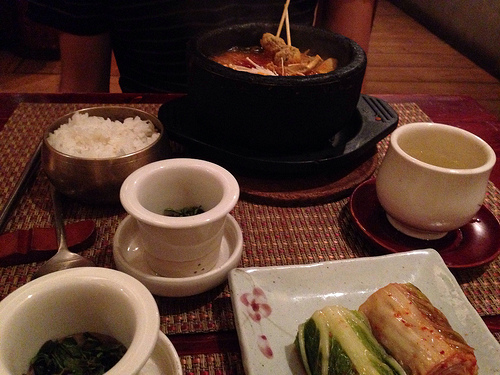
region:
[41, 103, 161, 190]
a bowl of white rice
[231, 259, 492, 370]
a plate of asian cuisine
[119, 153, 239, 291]
a thin white cup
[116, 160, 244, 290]
thin white cup on a ploatter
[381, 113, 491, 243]
a white tea cup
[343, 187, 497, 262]
a red plate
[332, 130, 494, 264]
a white tea cup on a red platter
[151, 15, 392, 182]
a black pot on a pot holder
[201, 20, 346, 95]
a pot of spicy looking food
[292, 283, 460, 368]
a plate of kimchi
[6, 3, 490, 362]
a traditional korean meal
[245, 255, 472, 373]
a plate of kimchi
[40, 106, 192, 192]
a bowl of rice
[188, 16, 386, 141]
a clay pot of stew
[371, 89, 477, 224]
a cup of green tea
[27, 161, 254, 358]
two dishes of ban chan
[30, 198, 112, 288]
a spoon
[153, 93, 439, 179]
a plate for carrying a hot dish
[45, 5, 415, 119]
a man in a black shirt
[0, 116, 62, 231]
a set of chopsticks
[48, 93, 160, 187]
rice in a bowl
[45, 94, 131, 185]
rice in a bowl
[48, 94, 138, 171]
rice in a bowl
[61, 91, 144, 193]
rice in a bowl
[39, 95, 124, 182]
rice in a bowl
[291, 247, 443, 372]
food on the plate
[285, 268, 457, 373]
food on the plate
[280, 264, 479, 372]
food on the plate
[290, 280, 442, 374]
food on the plate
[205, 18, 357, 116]
a portion of food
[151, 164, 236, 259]
a portion of food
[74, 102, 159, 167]
a portion of food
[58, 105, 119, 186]
a portion of food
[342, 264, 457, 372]
a portion of food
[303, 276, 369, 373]
a portion of food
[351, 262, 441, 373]
a portion of food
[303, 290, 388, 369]
a portion of food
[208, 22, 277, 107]
a portion of food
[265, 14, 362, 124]
a portion of food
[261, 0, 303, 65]
Mini meatballs with toothpicks sticking out of them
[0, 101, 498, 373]
Woven dark red and brown colored placemat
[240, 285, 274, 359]
Pink flower desing on the side of a square plate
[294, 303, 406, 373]
Green vegetable that is rolled and has wet exterior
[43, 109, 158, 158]
Medium serving of sticky white rice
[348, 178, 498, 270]
Dark maroon round saucer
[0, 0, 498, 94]
Brown hardwood floor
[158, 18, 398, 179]
Black bowl with a base used for serving hot food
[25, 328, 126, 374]
Wet green leafy substance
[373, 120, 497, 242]
Cream colored ceramic bowl with clear liquid in it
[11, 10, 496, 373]
a selection of food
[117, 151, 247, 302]
bowl in a saucer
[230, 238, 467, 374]
a plate of food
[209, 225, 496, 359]
the plate is square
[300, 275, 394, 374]
a green and tan veggie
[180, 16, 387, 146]
a black bowl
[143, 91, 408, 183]
plate under the bowl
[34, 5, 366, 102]
person sitting next to food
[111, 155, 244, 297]
small white pot sitting in white saucer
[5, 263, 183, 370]
small white pot filled with dirt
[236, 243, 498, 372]
square pottery plate with floral design